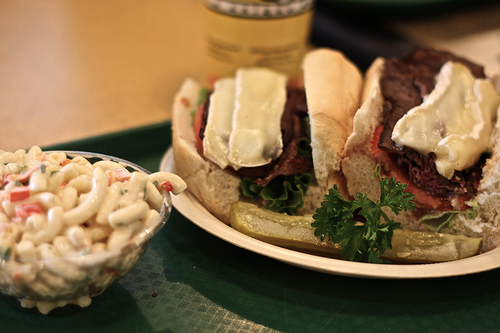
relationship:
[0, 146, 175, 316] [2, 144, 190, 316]
bowl of macaroni salad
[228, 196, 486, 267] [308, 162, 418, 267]
pickle covered with parsley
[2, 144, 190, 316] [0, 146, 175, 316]
macaroni salad on bowl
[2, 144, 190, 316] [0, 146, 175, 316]
macaroni salad in bowl